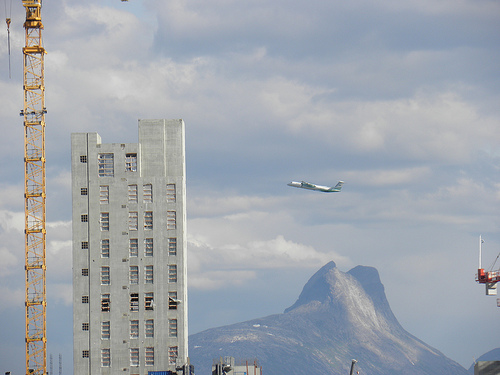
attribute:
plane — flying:
[282, 178, 344, 200]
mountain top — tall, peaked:
[303, 249, 402, 319]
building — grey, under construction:
[72, 117, 192, 371]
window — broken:
[98, 152, 115, 179]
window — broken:
[80, 152, 90, 173]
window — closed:
[80, 185, 92, 198]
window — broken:
[78, 212, 95, 227]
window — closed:
[126, 151, 138, 178]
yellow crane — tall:
[22, 1, 47, 373]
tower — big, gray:
[74, 106, 196, 304]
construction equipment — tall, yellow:
[21, 0, 48, 372]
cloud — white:
[4, 10, 495, 197]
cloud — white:
[0, 209, 353, 313]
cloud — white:
[149, 0, 498, 67]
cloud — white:
[319, 162, 451, 190]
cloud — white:
[4, 55, 486, 173]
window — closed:
[80, 215, 87, 222]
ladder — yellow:
[15, 42, 60, 365]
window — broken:
[98, 183, 108, 205]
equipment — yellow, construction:
[20, 2, 52, 374]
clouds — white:
[360, 69, 434, 132]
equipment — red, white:
[472, 231, 497, 296]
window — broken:
[166, 283, 181, 321]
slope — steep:
[344, 278, 434, 359]